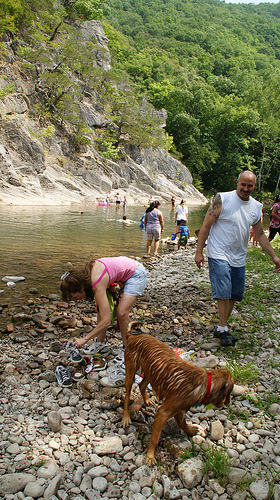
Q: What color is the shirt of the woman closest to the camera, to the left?
A: Pink.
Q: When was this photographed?
A: Daytime.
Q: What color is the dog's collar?
A: Red.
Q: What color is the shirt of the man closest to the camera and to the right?
A: White.